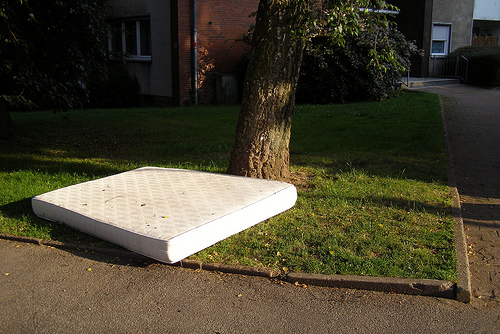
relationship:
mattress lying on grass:
[24, 159, 299, 269] [2, 84, 462, 282]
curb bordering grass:
[0, 83, 475, 302] [2, 84, 462, 282]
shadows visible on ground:
[1, 78, 492, 242] [5, 84, 494, 329]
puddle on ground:
[404, 50, 461, 95] [406, 76, 496, 221]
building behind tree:
[5, 3, 350, 126] [199, 0, 414, 199]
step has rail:
[407, 76, 453, 87] [397, 52, 411, 86]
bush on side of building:
[0, 0, 146, 111] [115, 2, 242, 112]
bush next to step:
[303, 9, 435, 94] [393, 72, 453, 87]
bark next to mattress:
[227, 1, 315, 184] [24, 161, 303, 281]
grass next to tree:
[2, 84, 462, 282] [221, 3, 402, 180]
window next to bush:
[104, 15, 154, 62] [2, 51, 144, 101]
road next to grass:
[1, 230, 499, 328] [2, 84, 462, 282]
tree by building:
[9, 20, 136, 113] [0, 0, 398, 107]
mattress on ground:
[24, 159, 299, 269] [5, 84, 494, 329]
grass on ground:
[2, 84, 462, 282] [242, 255, 428, 273]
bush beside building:
[233, 0, 423, 104] [0, 3, 477, 110]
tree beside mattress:
[223, 0, 334, 200] [30, 165, 298, 265]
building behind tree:
[93, 0, 499, 107] [227, 0, 363, 187]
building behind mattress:
[93, 0, 499, 107] [30, 165, 298, 265]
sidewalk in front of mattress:
[0, 234, 499, 332] [30, 165, 298, 265]